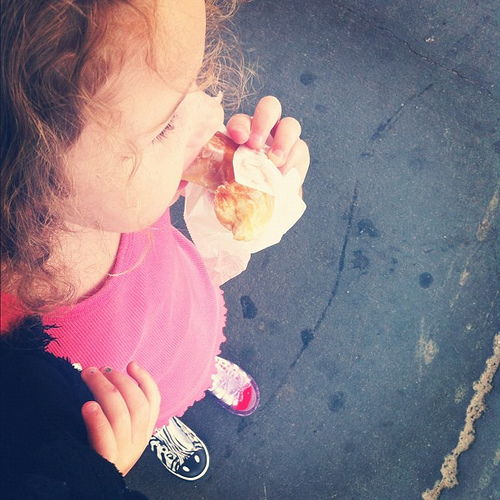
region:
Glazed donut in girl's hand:
[181, 105, 304, 239]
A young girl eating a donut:
[14, 0, 345, 476]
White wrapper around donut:
[136, 116, 312, 280]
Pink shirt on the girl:
[10, 204, 228, 428]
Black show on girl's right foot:
[133, 407, 219, 484]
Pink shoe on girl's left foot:
[193, 345, 270, 427]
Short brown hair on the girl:
[22, 0, 200, 300]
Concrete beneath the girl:
[257, 314, 399, 469]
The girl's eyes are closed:
[111, 100, 238, 159]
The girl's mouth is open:
[158, 122, 232, 201]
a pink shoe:
[197, 355, 270, 421]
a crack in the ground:
[422, 329, 499, 498]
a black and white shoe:
[152, 412, 206, 487]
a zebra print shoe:
[157, 427, 197, 468]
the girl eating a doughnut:
[182, 117, 279, 284]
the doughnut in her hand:
[190, 129, 314, 245]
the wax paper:
[184, 149, 307, 281]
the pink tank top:
[1, 214, 241, 425]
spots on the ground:
[285, 234, 467, 463]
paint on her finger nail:
[104, 362, 115, 380]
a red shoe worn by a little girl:
[196, 348, 270, 420]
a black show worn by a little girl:
[148, 411, 216, 478]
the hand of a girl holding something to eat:
[226, 96, 337, 253]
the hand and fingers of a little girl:
[71, 358, 168, 461]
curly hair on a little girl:
[11, 17, 141, 173]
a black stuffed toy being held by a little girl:
[8, 327, 143, 488]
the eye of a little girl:
[148, 97, 194, 149]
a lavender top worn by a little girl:
[62, 239, 246, 416]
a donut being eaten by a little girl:
[193, 134, 265, 243]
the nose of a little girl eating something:
[187, 82, 232, 153]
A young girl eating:
[22, 98, 327, 239]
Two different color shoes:
[135, 356, 288, 482]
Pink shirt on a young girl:
[11, 235, 245, 445]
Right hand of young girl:
[36, 357, 196, 480]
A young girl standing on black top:
[35, 72, 367, 492]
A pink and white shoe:
[185, 344, 282, 419]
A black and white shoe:
[126, 415, 240, 480]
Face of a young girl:
[13, 1, 249, 253]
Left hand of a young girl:
[171, 97, 353, 249]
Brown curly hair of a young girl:
[3, 0, 129, 330]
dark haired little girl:
[1, 0, 316, 481]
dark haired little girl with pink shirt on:
[1, 0, 312, 484]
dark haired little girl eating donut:
[1, 1, 320, 482]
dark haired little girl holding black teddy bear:
[1, 0, 311, 498]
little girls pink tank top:
[0, 206, 222, 434]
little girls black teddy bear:
[0, 313, 143, 498]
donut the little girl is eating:
[189, 129, 274, 243]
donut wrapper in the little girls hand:
[177, 121, 310, 288]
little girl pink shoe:
[209, 345, 267, 419]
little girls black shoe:
[144, 416, 217, 480]